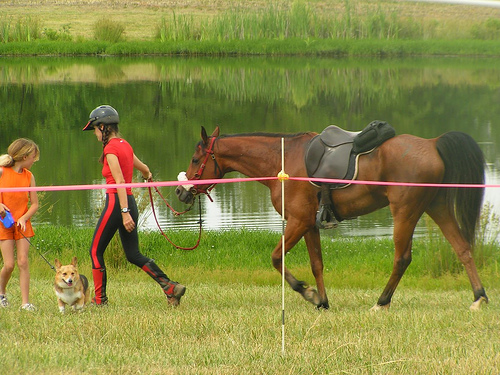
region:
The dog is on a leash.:
[0, 133, 94, 322]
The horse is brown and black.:
[173, 115, 491, 319]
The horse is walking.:
[172, 113, 493, 314]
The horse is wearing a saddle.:
[172, 115, 492, 317]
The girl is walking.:
[78, 99, 190, 311]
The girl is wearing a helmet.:
[78, 99, 190, 309]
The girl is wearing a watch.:
[83, 101, 138, 234]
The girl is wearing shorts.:
[0, 131, 45, 316]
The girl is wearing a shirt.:
[82, 102, 139, 202]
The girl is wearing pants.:
[81, 105, 186, 312]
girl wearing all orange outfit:
[1, 135, 40, 314]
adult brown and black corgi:
[49, 253, 89, 315]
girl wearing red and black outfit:
[83, 102, 147, 311]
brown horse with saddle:
[175, 123, 490, 321]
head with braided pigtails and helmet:
[80, 102, 117, 168]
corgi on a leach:
[1, 200, 92, 315]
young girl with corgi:
[2, 137, 91, 318]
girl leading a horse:
[84, 103, 489, 313]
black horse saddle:
[305, 119, 394, 188]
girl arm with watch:
[105, 148, 136, 235]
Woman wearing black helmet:
[73, 100, 190, 308]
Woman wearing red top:
[78, 105, 186, 314]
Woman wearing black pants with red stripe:
[80, 100, 190, 307]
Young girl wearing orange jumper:
[0, 140, 48, 316]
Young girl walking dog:
[0, 133, 41, 315]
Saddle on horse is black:
[301, 122, 358, 190]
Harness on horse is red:
[148, 128, 217, 262]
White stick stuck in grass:
[277, 134, 289, 359]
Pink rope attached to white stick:
[0, 170, 499, 210]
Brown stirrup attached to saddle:
[307, 183, 338, 231]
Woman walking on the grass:
[82, 105, 187, 307]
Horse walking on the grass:
[176, 124, 490, 311]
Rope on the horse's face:
[145, 135, 211, 250]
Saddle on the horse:
[302, 118, 392, 188]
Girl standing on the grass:
[0, 139, 40, 311]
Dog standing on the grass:
[51, 252, 88, 314]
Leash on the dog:
[0, 211, 55, 268]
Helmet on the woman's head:
[80, 104, 120, 132]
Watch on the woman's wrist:
[119, 207, 131, 213]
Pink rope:
[1, 174, 498, 191]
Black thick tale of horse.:
[438, 126, 485, 243]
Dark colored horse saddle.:
[302, 106, 386, 220]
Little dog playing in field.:
[47, 256, 91, 312]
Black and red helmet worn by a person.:
[81, 98, 120, 129]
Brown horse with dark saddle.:
[175, 121, 496, 316]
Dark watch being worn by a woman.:
[118, 205, 131, 216]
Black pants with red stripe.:
[86, 193, 151, 270]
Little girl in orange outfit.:
[0, 118, 40, 318]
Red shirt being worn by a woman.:
[96, 135, 138, 193]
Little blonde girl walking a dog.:
[1, 131, 88, 316]